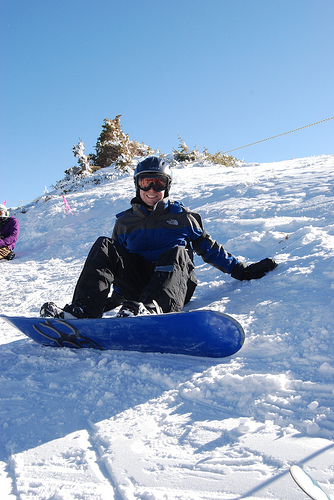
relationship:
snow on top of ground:
[254, 217, 291, 237] [91, 384, 252, 405]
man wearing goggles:
[65, 130, 210, 284] [139, 180, 170, 190]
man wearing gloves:
[65, 130, 210, 284] [68, 241, 278, 275]